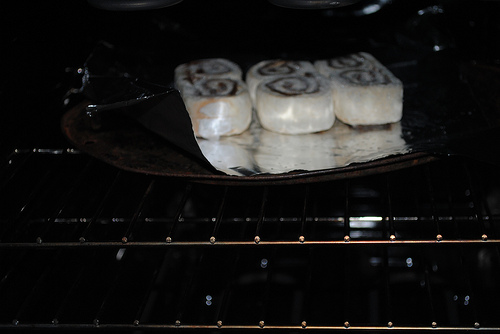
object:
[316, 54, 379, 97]
cinnamon roll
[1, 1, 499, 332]
oven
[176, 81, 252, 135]
cinnamon roll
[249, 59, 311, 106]
cinnamon roll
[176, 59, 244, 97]
cinnamon roll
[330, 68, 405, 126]
cinnamon roll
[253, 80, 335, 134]
cinnamon roll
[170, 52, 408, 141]
cinnamon rolls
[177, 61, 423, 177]
foil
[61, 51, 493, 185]
pan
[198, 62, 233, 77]
design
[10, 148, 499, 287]
rack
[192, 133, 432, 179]
reflection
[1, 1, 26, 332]
wall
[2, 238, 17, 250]
spoke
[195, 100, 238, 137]
orange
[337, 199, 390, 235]
spot